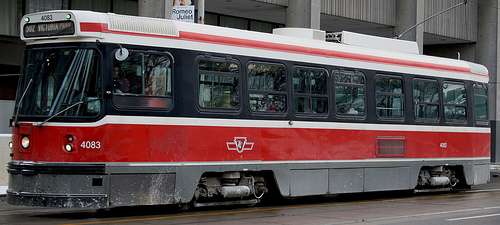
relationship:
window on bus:
[237, 58, 290, 125] [6, 10, 492, 214]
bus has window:
[19, 11, 472, 171] [363, 70, 403, 127]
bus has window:
[6, 10, 492, 214] [187, 50, 247, 116]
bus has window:
[6, 10, 492, 214] [132, 50, 491, 130]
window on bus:
[101, 41, 176, 111] [6, 10, 492, 214]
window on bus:
[237, 58, 290, 116] [6, 10, 492, 214]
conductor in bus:
[105, 64, 140, 111] [6, 10, 492, 214]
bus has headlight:
[6, 10, 492, 214] [18, 134, 30, 154]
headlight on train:
[7, 132, 75, 154] [4, 5, 496, 224]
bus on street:
[6, 10, 492, 214] [94, 187, 499, 223]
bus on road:
[6, 10, 492, 214] [93, 178, 498, 219]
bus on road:
[6, 10, 492, 214] [7, 180, 497, 224]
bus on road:
[6, 10, 492, 214] [8, 176, 496, 222]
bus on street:
[6, 10, 492, 214] [134, 190, 499, 224]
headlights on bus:
[3, 132, 85, 160] [6, 10, 492, 214]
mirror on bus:
[112, 44, 145, 67] [6, 10, 492, 214]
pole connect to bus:
[398, 2, 468, 29] [6, 10, 492, 214]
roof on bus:
[119, 14, 490, 79] [6, 10, 492, 214]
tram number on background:
[72, 139, 109, 149] [14, 128, 494, 163]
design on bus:
[225, 135, 255, 152] [6, 10, 492, 214]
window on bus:
[194, 55, 244, 112] [6, 10, 492, 214]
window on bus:
[294, 69, 329, 113] [6, 10, 492, 214]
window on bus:
[363, 70, 409, 121] [6, 10, 492, 214]